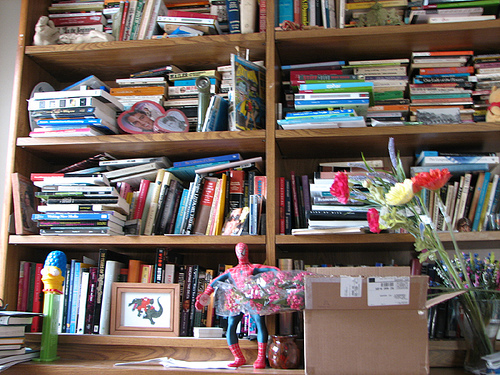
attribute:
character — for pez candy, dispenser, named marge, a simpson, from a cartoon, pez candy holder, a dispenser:
[40, 251, 65, 360]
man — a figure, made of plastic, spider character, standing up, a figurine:
[195, 243, 284, 369]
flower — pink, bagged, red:
[329, 170, 350, 204]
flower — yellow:
[385, 178, 416, 206]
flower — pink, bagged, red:
[411, 167, 451, 191]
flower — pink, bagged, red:
[367, 207, 380, 232]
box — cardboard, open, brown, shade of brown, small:
[304, 266, 467, 372]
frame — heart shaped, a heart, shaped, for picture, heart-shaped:
[155, 106, 190, 134]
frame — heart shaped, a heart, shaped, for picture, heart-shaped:
[117, 101, 165, 133]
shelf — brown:
[275, 123, 496, 139]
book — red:
[134, 180, 150, 220]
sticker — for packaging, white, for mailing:
[368, 277, 410, 306]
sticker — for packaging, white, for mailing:
[341, 273, 364, 297]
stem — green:
[404, 204, 489, 347]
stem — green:
[433, 191, 493, 352]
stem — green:
[348, 188, 427, 231]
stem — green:
[389, 224, 420, 247]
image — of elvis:
[162, 118, 185, 128]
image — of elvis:
[128, 110, 154, 129]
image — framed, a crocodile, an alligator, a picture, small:
[127, 297, 163, 325]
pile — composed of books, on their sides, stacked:
[4, 311, 38, 370]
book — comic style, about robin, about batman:
[233, 53, 265, 130]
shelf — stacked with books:
[17, 131, 268, 145]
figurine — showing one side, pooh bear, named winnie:
[488, 88, 498, 121]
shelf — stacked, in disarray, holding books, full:
[6, 141, 269, 243]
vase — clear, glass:
[447, 298, 497, 372]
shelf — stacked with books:
[27, 32, 268, 54]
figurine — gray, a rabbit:
[350, 4, 403, 28]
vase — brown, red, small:
[266, 333, 298, 369]